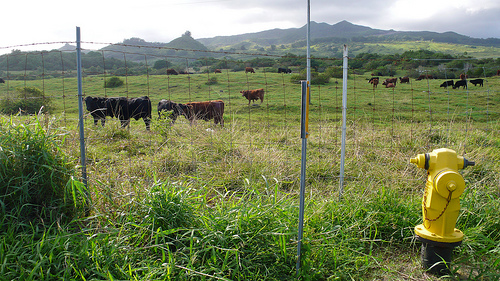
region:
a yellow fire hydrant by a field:
[408, 146, 477, 243]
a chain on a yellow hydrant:
[422, 185, 454, 222]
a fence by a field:
[1, 27, 498, 215]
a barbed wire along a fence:
[1, 40, 498, 57]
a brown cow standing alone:
[239, 86, 266, 105]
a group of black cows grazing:
[438, 78, 484, 89]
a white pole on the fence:
[338, 42, 348, 202]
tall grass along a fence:
[1, 175, 498, 279]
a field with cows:
[2, 70, 499, 158]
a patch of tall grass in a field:
[203, 73, 219, 86]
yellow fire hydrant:
[406, 133, 481, 265]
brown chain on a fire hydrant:
[410, 183, 449, 231]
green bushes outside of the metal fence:
[3, 116, 489, 276]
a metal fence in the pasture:
[3, 33, 498, 243]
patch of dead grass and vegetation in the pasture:
[11, 100, 496, 213]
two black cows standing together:
[80, 86, 157, 131]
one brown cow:
[233, 81, 272, 106]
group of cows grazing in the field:
[54, 48, 492, 122]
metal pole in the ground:
[278, 2, 323, 264]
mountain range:
[98, 12, 485, 56]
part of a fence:
[340, 113, 357, 132]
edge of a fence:
[165, 110, 192, 142]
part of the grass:
[137, 230, 152, 251]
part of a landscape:
[325, 13, 343, 31]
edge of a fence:
[111, 120, 130, 155]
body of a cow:
[113, 88, 133, 120]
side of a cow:
[188, 91, 200, 122]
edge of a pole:
[292, 210, 305, 232]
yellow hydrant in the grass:
[392, 139, 483, 252]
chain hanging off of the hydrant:
[420, 193, 450, 228]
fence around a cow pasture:
[3, 24, 497, 254]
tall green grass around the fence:
[2, 113, 499, 280]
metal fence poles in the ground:
[77, 25, 89, 231]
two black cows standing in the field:
[79, 83, 153, 131]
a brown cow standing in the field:
[236, 73, 273, 112]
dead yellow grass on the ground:
[24, 113, 489, 210]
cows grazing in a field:
[85, 63, 495, 130]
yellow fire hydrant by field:
[0, 141, 80, 233]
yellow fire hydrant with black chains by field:
[403, 134, 467, 271]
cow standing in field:
[0, 85, 37, 103]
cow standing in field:
[239, 79, 270, 110]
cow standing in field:
[189, 94, 229, 129]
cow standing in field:
[156, 93, 178, 128]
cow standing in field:
[86, 84, 150, 132]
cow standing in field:
[367, 75, 382, 95]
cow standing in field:
[467, 71, 487, 88]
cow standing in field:
[433, 77, 454, 96]